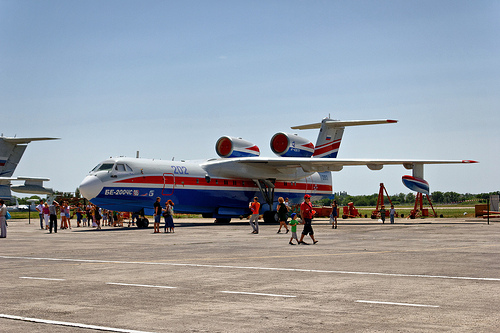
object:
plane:
[56, 112, 479, 228]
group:
[153, 196, 175, 233]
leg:
[309, 229, 316, 241]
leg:
[300, 228, 308, 239]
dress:
[276, 212, 289, 222]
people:
[277, 197, 291, 234]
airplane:
[0, 133, 63, 205]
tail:
[289, 113, 396, 158]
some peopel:
[35, 193, 396, 245]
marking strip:
[19, 276, 66, 281]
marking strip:
[104, 280, 177, 290]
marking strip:
[352, 298, 438, 308]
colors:
[88, 175, 332, 219]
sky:
[0, 0, 499, 190]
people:
[248, 197, 261, 234]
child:
[288, 213, 302, 245]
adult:
[297, 193, 319, 244]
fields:
[3, 204, 500, 282]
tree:
[73, 187, 81, 204]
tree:
[338, 191, 348, 208]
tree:
[397, 192, 405, 204]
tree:
[406, 193, 414, 203]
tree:
[442, 190, 452, 202]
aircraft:
[78, 113, 480, 228]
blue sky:
[2, 0, 498, 196]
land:
[0, 201, 499, 331]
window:
[89, 163, 133, 174]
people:
[49, 199, 59, 233]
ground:
[0, 219, 497, 330]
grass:
[358, 208, 458, 216]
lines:
[215, 291, 298, 300]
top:
[289, 112, 398, 130]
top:
[92, 113, 478, 170]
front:
[76, 154, 146, 213]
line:
[0, 253, 500, 283]